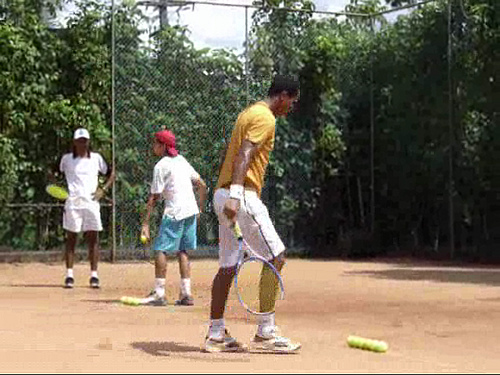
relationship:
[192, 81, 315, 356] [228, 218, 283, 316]
man holding racket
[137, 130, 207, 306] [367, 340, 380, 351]
boy holding balls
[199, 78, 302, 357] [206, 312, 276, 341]
man wearing socks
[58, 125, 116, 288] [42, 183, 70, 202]
man holding tennis racket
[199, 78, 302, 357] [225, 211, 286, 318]
man holding racket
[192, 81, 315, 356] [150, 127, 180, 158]
man wearing cap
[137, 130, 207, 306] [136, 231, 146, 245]
boy holding ball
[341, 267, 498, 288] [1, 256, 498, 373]
shadow on court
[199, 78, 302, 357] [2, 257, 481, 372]
man on tennis court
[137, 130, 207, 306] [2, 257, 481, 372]
boy on tennis court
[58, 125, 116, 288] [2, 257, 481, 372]
man on tennis court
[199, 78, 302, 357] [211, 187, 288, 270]
man wearing shorts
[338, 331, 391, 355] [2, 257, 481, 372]
balls on tennis court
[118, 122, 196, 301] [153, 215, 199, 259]
boy wearing shorts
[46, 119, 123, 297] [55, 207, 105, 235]
man wearing shorts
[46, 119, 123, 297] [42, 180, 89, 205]
man holding racket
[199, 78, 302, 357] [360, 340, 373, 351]
man playing balls